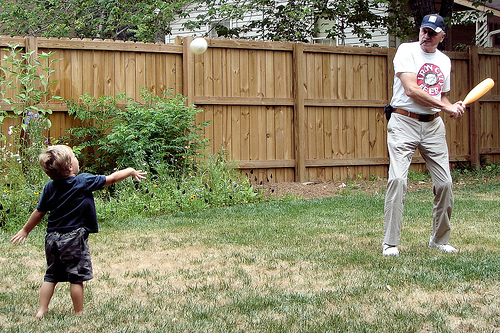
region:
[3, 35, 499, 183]
a wooden fence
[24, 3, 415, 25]
trees behind the fence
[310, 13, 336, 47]
a window on the house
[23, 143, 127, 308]
a child throwing a ball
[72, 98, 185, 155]
bushes in front of the fence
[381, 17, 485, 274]
a man holding a baseball bat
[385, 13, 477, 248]
a man wearing a hat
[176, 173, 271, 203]
flowers next to the fence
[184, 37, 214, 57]
a ball in the air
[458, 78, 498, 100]
a baseball bat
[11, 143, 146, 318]
a young blonde haired boy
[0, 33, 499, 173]
a tall wooden privacy fence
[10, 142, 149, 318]
a young boy wearing a navy blue shirt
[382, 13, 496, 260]
an older man holding a yellow bat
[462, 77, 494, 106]
a plastic yellow bat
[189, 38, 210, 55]
a white baseball in midair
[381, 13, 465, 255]
a man wearing a white shirt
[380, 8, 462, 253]
a man wearing a ball cap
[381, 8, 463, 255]
a man wearing khaki pants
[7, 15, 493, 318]
a man and a boy playing baseball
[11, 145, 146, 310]
little boy throwing a ball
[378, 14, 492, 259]
old man swinging a bat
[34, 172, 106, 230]
blue shirt on the boy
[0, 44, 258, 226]
bushes growing against the fence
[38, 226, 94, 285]
gray shorts on the boy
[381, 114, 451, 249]
tans pants on the man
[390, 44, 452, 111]
red and white t-shirt on the man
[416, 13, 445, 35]
black and white hat on the man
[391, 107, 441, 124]
brown belt on the man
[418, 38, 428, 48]
cigar in the man's mouth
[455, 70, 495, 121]
the bat is brown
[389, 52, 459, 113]
his shirt is white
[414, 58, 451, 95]
the logo is red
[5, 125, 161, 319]
the kid stands oddly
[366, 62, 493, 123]
ready to hit the ball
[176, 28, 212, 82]
the ball is white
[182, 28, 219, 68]
the ball is in the air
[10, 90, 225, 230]
he threw the ball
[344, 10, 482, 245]
he is playing baseball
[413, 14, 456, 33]
his hat is blue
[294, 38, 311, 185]
post on the fence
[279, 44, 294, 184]
post on the fence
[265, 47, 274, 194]
post on the fence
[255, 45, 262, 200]
post on the fence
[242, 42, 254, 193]
post on the fence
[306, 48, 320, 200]
post on the fence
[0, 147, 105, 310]
child throwing the ball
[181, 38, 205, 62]
ball in the air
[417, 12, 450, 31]
hat on the head